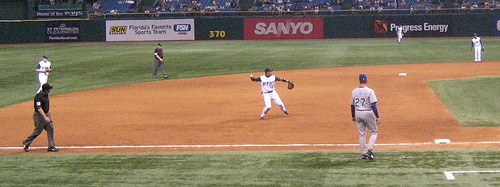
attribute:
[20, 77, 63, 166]
umpire — watching, close, white, walking, fat, big, looking, standing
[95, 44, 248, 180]
field — brown, dirt, dark, close, green, orange, neat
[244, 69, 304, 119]
player — throwing, playing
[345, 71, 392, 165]
coach — watching, standing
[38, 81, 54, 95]
cap — black